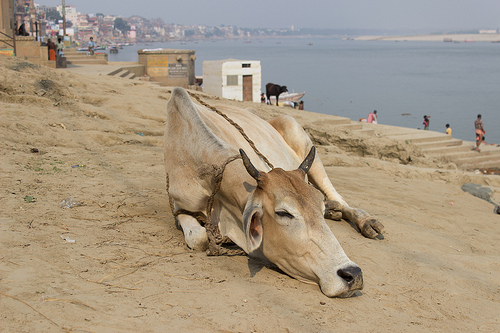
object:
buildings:
[15, 0, 326, 51]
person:
[474, 113, 486, 152]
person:
[442, 122, 453, 135]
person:
[423, 114, 431, 130]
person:
[368, 109, 379, 124]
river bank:
[100, 55, 500, 151]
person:
[87, 36, 95, 55]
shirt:
[87, 40, 96, 51]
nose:
[337, 265, 365, 290]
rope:
[174, 88, 274, 256]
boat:
[264, 89, 306, 102]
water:
[107, 32, 499, 156]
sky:
[30, 0, 500, 34]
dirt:
[0, 51, 499, 331]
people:
[357, 109, 486, 152]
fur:
[200, 116, 256, 172]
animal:
[164, 85, 384, 299]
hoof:
[362, 218, 384, 238]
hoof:
[324, 200, 343, 221]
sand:
[0, 57, 499, 333]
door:
[240, 74, 255, 100]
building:
[202, 57, 262, 103]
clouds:
[33, 0, 499, 33]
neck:
[204, 157, 261, 253]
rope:
[204, 150, 244, 259]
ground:
[0, 52, 499, 332]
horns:
[238, 145, 316, 179]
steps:
[107, 66, 148, 89]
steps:
[63, 47, 118, 71]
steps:
[306, 107, 499, 174]